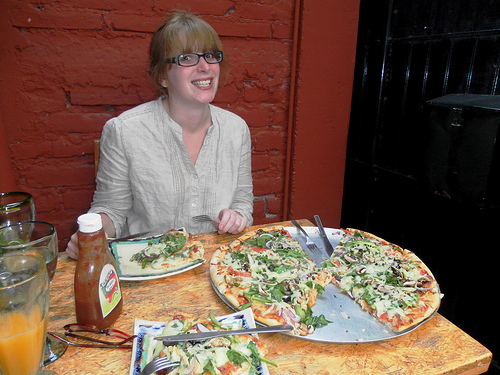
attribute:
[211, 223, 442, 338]
pizza — missing pieces, spicy, big, sliced, slized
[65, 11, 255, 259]
lady — smiling, light skinned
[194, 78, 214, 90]
mouth — open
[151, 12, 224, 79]
hair — pale brown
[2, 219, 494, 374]
table — wooden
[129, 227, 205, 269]
pizza — partially eaten, partly eaten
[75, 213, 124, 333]
bottle of sauce — squeeze brand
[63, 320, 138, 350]
eye glasses — red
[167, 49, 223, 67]
eye glasses — dark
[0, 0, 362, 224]
wall — red